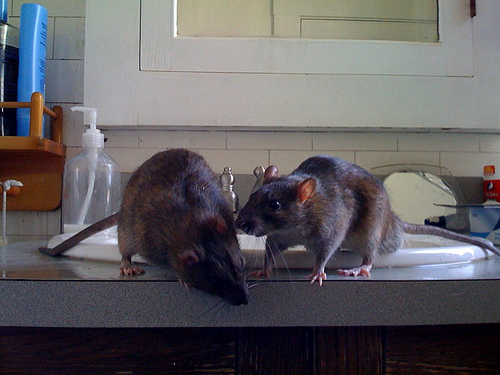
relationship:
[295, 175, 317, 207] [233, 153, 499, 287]
ear of a big rat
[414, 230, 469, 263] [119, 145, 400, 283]
sink has two rodents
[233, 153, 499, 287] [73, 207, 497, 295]
big rat on sink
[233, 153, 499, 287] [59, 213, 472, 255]
big rat on sink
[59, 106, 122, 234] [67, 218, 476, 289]
bottle on sink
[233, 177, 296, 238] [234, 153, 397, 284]
face of rat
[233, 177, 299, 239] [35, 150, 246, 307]
face of rat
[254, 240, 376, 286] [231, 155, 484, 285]
legs of rat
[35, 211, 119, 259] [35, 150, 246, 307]
tail of rat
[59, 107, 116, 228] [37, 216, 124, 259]
bottle obstructed by tail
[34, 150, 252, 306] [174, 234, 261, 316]
rodent with head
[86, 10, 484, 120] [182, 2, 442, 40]
chest with mirror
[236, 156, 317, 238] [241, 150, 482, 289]
head of mice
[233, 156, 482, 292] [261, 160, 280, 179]
ear of mice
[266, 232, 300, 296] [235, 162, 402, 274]
whisker of mouse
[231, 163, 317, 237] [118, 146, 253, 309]
head of mouse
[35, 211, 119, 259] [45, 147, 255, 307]
tail of mouse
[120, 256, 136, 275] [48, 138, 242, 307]
foot of mouse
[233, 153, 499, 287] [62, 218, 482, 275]
big rat on sink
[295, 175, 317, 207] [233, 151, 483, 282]
ear of mouse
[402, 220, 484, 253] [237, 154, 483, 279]
tail of animal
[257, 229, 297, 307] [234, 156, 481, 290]
wiskers on animal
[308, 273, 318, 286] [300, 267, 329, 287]
toe on foot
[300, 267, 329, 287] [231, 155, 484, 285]
foot of rat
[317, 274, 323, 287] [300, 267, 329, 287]
toe of foot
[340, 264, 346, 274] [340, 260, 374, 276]
toe of foot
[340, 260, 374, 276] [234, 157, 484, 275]
foot of rat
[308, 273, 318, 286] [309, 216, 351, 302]
toe on rats foot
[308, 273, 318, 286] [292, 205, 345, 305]
toe on rats foot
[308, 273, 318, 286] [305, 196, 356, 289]
toe on rats foot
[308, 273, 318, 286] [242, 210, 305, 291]
toe on rats foot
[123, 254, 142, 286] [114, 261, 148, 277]
toe on foot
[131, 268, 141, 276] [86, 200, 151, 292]
toe on rats foot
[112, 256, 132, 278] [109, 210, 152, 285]
toe on rats foot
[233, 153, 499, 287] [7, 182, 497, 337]
big rat on counter top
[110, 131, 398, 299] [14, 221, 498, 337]
two rats on counter top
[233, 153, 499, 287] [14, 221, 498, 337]
big rat on counter top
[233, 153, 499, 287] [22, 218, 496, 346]
big rat on counter top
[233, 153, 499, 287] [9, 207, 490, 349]
big rat on counter top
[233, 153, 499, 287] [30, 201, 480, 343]
big rat on counter top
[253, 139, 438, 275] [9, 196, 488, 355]
big rat on counter top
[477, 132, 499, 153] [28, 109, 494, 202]
ceramic tile on wall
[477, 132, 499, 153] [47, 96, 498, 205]
ceramic tile on wall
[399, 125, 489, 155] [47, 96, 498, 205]
ceramic tile on wall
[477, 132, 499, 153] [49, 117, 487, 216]
ceramic tile on wall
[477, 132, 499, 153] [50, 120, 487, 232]
ceramic tile on wall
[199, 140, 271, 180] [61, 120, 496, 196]
ceramic tile on wall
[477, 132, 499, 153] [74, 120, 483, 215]
ceramic tile on wall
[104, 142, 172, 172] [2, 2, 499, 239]
tile on wall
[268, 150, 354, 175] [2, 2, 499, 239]
tile on wall